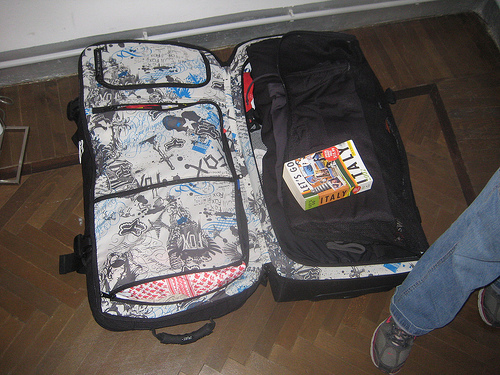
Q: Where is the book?
A: On the bag.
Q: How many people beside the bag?
A: One.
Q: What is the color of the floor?
A: Brown.